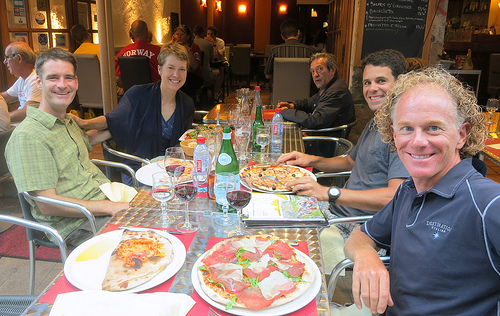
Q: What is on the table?
A: Food and drinks.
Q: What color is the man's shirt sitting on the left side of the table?
A: Green.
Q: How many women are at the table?
A: 1.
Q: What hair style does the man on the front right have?
A: Curly.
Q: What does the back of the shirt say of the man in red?
A: Norway.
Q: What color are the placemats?
A: Red.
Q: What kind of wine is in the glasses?
A: Red.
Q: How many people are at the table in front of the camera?
A: 5.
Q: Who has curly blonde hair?
A: The first man on the right.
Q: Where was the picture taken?
A: A restaurant.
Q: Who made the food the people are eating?
A: A chef.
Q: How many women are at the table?
A: 1.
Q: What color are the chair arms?
A: Silver.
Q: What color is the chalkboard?
A: Black.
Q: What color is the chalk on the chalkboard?
A: White.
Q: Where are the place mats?
A: Under the plates.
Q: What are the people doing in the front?
A: Smiling.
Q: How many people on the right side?
A: Three.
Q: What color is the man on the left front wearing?
A: Green.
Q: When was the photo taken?
A: Lunch time.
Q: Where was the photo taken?
A: A restaurant.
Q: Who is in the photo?
A: Men and women.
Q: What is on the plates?
A: Pizza.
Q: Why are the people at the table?
A: To eat.